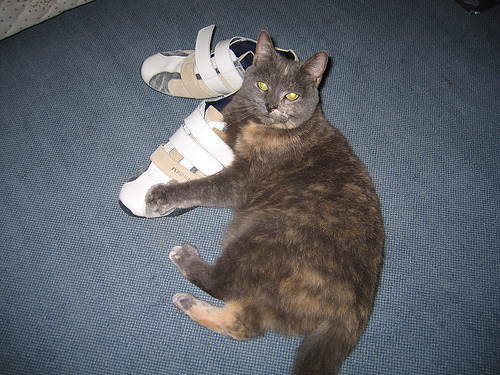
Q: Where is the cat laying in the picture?
A: Center.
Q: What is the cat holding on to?
A: Sandal.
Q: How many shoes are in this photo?
A: 2.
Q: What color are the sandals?
A: White.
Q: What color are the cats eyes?
A: Green.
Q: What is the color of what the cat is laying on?
A: Blue.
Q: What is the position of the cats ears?
A: Upright.